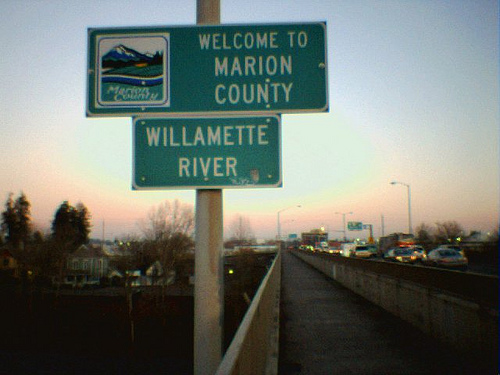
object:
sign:
[89, 24, 328, 116]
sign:
[130, 109, 283, 189]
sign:
[348, 221, 364, 232]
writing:
[196, 29, 307, 106]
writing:
[142, 122, 272, 178]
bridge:
[217, 251, 500, 373]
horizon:
[3, 206, 500, 260]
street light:
[390, 180, 414, 235]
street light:
[276, 208, 288, 235]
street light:
[334, 211, 353, 241]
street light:
[381, 215, 385, 238]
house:
[52, 244, 110, 291]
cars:
[295, 235, 473, 270]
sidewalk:
[275, 242, 445, 374]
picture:
[97, 32, 171, 108]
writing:
[107, 83, 160, 102]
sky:
[3, 2, 499, 182]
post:
[190, 0, 228, 373]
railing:
[207, 250, 284, 372]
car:
[421, 249, 470, 271]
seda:
[354, 249, 372, 258]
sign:
[289, 233, 297, 238]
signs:
[80, 22, 330, 187]